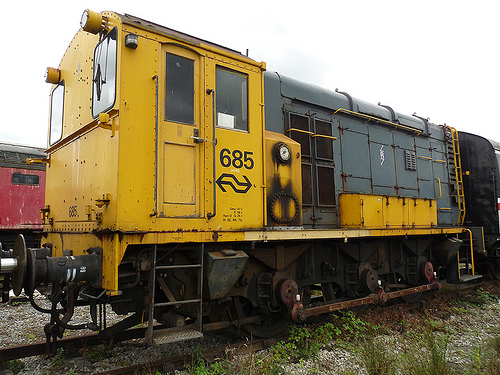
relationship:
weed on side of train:
[275, 314, 330, 363] [38, 8, 499, 319]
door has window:
[149, 43, 207, 224] [160, 53, 198, 130]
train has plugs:
[38, 8, 499, 319] [4, 241, 104, 297]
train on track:
[38, 8, 499, 319] [3, 273, 494, 369]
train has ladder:
[38, 8, 499, 319] [441, 119, 467, 224]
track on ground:
[3, 273, 494, 369] [15, 280, 499, 372]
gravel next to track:
[288, 306, 499, 370] [3, 273, 494, 369]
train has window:
[38, 8, 499, 319] [216, 64, 250, 127]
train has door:
[38, 8, 499, 319] [149, 43, 207, 224]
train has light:
[38, 8, 499, 319] [75, 9, 106, 34]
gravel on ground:
[288, 306, 499, 370] [15, 280, 499, 372]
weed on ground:
[275, 314, 330, 363] [15, 280, 499, 372]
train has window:
[38, 8, 499, 319] [92, 26, 121, 114]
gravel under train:
[288, 306, 499, 370] [38, 8, 499, 319]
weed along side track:
[275, 314, 330, 363] [3, 273, 494, 369]